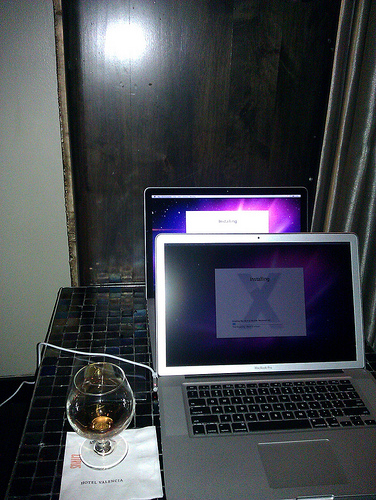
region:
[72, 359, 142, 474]
the glass on the napkin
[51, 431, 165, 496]
the napkin is white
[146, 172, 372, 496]
the laptops are on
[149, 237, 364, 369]
screen of the laptop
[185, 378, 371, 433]
the keyboard of the laptop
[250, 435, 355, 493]
the track pad of the laptop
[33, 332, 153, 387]
the cable connected to the laptop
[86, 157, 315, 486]
laptops on a table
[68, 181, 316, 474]
two macbooks on a table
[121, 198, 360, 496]
open macbooks on a table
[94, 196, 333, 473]
silver macbooks on a table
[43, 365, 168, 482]
a glass of wine on the table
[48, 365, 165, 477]
a glass on the table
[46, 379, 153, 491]
a wine glass on the table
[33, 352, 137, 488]
a glass of wine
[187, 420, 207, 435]
Black and white key on laptop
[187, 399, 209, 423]
Black and white key on laptop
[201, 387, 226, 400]
Black and white key on laptop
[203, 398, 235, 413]
Black and white key on laptop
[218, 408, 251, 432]
Black and white key on laptop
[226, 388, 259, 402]
Black and white key on laptop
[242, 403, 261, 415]
Black and white key on laptop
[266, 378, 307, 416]
Black and white key on laptop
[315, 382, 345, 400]
Black and white key on laptop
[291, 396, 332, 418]
Black and white key on laptop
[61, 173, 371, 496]
Two laptop computers on a black tiled table with a glass of wine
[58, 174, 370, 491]
Two laptop computers on a black tiled table with a glass of wine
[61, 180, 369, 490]
Two laptop computers on a black tiled table with a glass of wine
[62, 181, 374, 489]
Two laptop computers on a black tiled table with a glass of wine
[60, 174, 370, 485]
Two laptop computers on a black tiled table with a glass of wine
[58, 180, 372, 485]
Two laptop computers on a black tiled table with a glass of wine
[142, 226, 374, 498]
laptop on a table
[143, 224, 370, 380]
screen of laptop is on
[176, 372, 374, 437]
keyboard of laptop is black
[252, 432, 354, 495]
touchpad of laptop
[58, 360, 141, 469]
a cup of glass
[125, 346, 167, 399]
wire connected to laptop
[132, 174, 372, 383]
two screens of laptops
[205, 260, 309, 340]
an X on screen of laptop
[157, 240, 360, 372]
laptop screen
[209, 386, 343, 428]
keys on the keyboard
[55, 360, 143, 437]
a wine glass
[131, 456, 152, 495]
a white paper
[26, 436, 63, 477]
bricks are black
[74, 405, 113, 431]
liquid in the glass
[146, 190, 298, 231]
a laptop screen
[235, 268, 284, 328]
an X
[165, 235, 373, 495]
laptop is grey and black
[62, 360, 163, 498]
half full wine glass sitting on napkin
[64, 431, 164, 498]
Napkin branded with Hotel Valencia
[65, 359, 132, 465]
wine glass filled with light amber liquid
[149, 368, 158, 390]
end of power cord adapter with glowing red LED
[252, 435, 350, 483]
grey square laptop touchpad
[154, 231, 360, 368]
laptop monitor with white border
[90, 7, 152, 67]
reflection of light bulb on dark wood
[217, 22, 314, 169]
dark, almost black stained wooden door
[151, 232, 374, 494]
laptop displaying software installation screen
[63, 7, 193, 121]
light hitting the door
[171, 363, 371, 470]
keys on the keyboard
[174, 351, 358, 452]
black and white keys